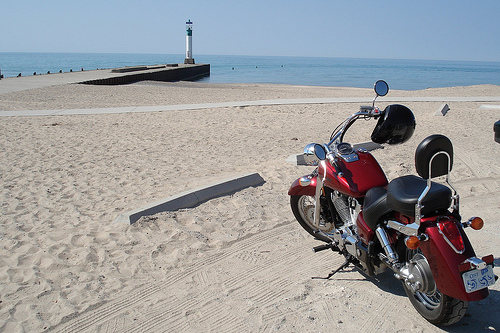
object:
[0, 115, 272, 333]
concrete block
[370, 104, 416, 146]
helmet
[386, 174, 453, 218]
seat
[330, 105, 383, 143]
handlebar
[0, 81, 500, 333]
beach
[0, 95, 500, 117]
sidewalk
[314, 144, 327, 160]
mirror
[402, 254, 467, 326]
rear wheel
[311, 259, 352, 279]
kick stand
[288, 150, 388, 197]
red trim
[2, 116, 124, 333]
footprints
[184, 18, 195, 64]
light house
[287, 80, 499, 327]
motorcycle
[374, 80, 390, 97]
mirror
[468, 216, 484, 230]
light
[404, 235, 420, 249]
light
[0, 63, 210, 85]
pier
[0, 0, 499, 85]
ocean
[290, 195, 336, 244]
tire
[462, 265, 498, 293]
license plate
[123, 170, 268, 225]
curb market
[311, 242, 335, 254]
brake